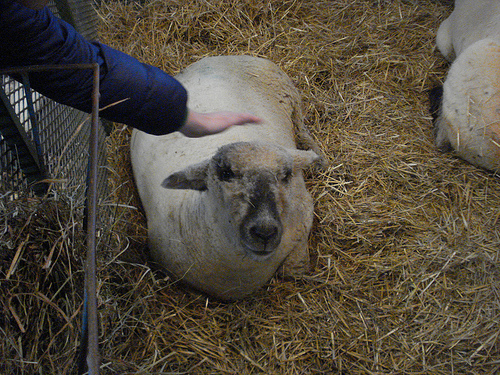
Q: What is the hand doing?
A: Reaching.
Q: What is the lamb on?
A: Hay.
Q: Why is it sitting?
A: Relaxing.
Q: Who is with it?
A: Person.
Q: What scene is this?
A: Barn.